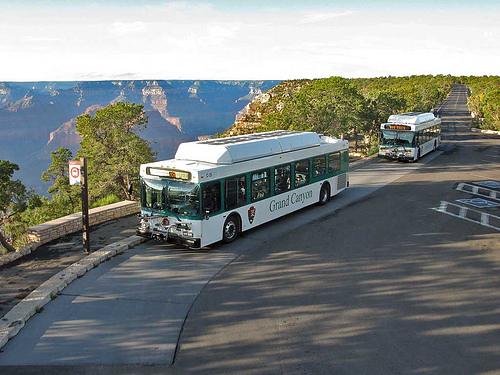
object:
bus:
[129, 125, 356, 251]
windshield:
[140, 175, 164, 210]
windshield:
[166, 184, 197, 215]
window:
[329, 153, 343, 175]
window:
[311, 157, 327, 178]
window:
[293, 162, 309, 189]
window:
[275, 165, 293, 192]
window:
[248, 172, 270, 198]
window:
[224, 178, 246, 206]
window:
[202, 186, 222, 212]